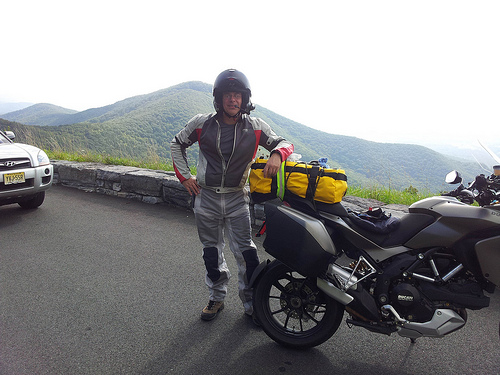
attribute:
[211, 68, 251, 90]
helmet — black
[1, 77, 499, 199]
mountains — in the distance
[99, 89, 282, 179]
hill — green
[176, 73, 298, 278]
man — wearing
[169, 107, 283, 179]
jacket — gray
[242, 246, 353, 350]
wheel — black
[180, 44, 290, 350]
man — wearing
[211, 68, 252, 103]
helmet — black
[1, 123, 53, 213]
suv — small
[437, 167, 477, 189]
mirror — side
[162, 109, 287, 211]
jacket — grey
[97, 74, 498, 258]
mountains — in the background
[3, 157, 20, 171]
logo — silver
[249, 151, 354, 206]
bag — black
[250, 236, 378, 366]
wheel — black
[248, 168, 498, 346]
motorcycle — black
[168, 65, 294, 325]
man — looking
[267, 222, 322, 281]
tank — gas